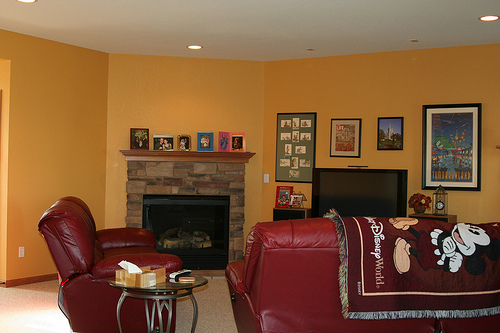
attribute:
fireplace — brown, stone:
[122, 142, 256, 272]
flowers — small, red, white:
[371, 184, 440, 222]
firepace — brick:
[119, 147, 244, 279]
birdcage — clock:
[432, 182, 450, 214]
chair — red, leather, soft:
[33, 189, 158, 322]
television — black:
[302, 160, 419, 223]